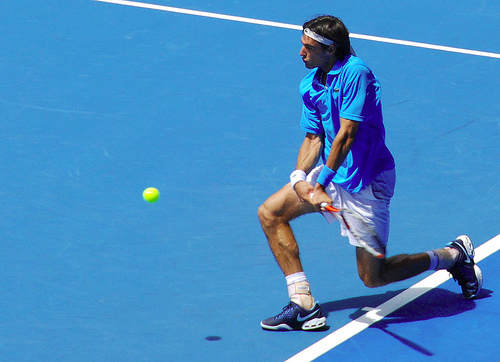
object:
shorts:
[306, 163, 391, 259]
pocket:
[355, 182, 385, 202]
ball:
[142, 186, 160, 203]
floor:
[2, 0, 497, 360]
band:
[302, 27, 334, 45]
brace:
[287, 280, 315, 309]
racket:
[309, 191, 386, 258]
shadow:
[319, 285, 493, 358]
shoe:
[258, 299, 328, 334]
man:
[258, 12, 485, 333]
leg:
[349, 189, 443, 288]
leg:
[254, 183, 324, 300]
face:
[298, 28, 335, 70]